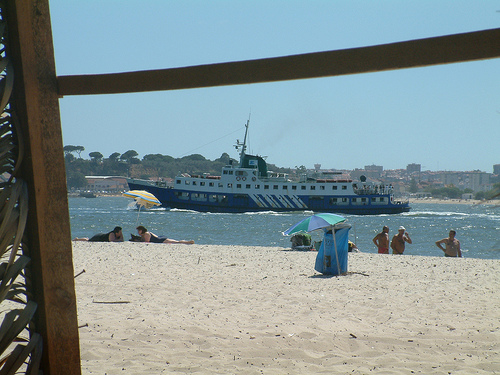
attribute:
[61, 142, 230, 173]
trees — distant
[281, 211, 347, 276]
umbrella — green, white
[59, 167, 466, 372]
scene — beach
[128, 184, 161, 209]
umbrella — orange and blue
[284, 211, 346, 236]
umbrella — sun umbrella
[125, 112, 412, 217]
ship — sailing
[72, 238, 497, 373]
beach — crowded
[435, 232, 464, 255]
man — shirtless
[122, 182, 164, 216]
yellow umbrella — beach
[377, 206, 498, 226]
surf — white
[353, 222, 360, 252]
pole — long, thin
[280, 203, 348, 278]
umbrella — blue and green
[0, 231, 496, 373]
beach — sandy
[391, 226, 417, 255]
hat — white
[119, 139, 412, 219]
cruise ship — big, blue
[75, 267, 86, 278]
nail — wooden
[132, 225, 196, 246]
woman — laying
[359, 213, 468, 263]
men — middle-aged, walking by, trunk-wearers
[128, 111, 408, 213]
watercraft — blue, white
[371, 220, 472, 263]
three men — standing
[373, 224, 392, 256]
man — balding, shirtless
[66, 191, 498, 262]
water — ocean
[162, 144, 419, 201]
ship — passing 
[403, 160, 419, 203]
building — distant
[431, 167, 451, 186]
building — distant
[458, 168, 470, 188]
building — distant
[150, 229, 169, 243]
suit — dark, bathing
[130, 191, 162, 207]
piping — blue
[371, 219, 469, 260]
group — men, chatting